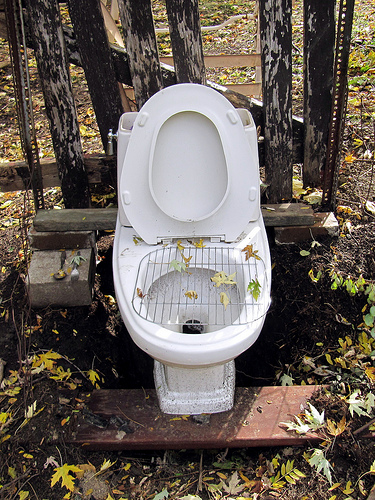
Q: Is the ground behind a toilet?
A: Yes, the ground is behind a toilet.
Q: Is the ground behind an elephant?
A: No, the ground is behind a toilet.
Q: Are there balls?
A: No, there are no balls.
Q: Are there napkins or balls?
A: No, there are no balls or napkins.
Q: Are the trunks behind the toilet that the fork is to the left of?
A: Yes, the trunks are behind the toilet.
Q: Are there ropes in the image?
A: No, there are no ropes.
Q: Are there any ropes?
A: No, there are no ropes.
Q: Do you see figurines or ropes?
A: No, there are no ropes or figurines.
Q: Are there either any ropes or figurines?
A: No, there are no ropes or figurines.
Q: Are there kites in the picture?
A: No, there are no kites.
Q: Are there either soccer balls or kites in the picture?
A: No, there are no kites or soccer balls.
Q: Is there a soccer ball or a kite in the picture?
A: No, there are no kites or soccer balls.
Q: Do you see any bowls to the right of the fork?
A: Yes, there is a bowl to the right of the fork.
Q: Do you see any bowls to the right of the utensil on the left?
A: Yes, there is a bowl to the right of the fork.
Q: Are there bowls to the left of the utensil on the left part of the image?
A: No, the bowl is to the right of the fork.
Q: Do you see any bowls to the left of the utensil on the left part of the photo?
A: No, the bowl is to the right of the fork.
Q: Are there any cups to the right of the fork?
A: No, there is a bowl to the right of the fork.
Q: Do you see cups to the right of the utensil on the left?
A: No, there is a bowl to the right of the fork.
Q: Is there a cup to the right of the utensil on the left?
A: No, there is a bowl to the right of the fork.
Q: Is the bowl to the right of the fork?
A: Yes, the bowl is to the right of the fork.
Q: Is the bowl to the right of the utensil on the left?
A: Yes, the bowl is to the right of the fork.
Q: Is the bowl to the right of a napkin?
A: No, the bowl is to the right of the fork.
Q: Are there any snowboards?
A: No, there are no snowboards.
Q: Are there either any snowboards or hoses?
A: No, there are no snowboards or hoses.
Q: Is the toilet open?
A: Yes, the toilet is open.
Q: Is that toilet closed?
A: No, the toilet is open.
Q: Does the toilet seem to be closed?
A: No, the toilet is open.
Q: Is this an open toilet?
A: Yes, this is an open toilet.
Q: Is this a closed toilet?
A: No, this is an open toilet.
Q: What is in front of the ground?
A: The toilet is in front of the ground.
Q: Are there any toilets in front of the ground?
A: Yes, there is a toilet in front of the ground.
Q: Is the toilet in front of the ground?
A: Yes, the toilet is in front of the ground.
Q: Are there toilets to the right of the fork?
A: Yes, there is a toilet to the right of the fork.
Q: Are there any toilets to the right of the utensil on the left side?
A: Yes, there is a toilet to the right of the fork.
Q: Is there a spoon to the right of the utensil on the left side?
A: No, there is a toilet to the right of the fork.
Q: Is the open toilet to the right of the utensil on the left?
A: Yes, the toilet is to the right of the fork.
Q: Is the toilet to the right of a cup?
A: No, the toilet is to the right of the fork.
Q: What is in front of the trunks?
A: The toilet is in front of the trunks.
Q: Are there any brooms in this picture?
A: No, there are no brooms.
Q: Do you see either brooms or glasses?
A: No, there are no brooms or glasses.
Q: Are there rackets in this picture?
A: No, there are no rackets.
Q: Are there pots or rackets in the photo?
A: No, there are no rackets or pots.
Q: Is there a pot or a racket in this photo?
A: No, there are no rackets or pots.